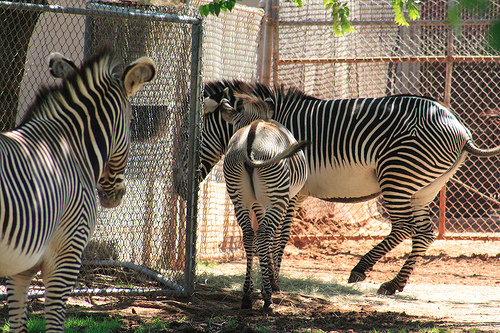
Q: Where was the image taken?
A: It was taken at the pen.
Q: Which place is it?
A: It is a pen.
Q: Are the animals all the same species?
A: Yes, all the animals are zebras.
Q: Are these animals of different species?
A: No, all the animals are zebras.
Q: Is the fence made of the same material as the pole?
A: Yes, both the fence and the pole are made of metal.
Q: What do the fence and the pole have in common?
A: The material, both the fence and the pole are metallic.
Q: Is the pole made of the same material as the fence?
A: Yes, both the pole and the fence are made of metal.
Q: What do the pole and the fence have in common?
A: The material, both the pole and the fence are metallic.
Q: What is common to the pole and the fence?
A: The material, both the pole and the fence are metallic.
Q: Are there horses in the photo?
A: No, there are no horses.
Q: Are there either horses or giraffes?
A: No, there are no horses or giraffes.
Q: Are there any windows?
A: Yes, there is a window.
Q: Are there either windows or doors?
A: Yes, there is a window.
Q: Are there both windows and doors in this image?
A: No, there is a window but no doors.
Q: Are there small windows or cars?
A: Yes, there is a small window.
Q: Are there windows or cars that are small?
A: Yes, the window is small.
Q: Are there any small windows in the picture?
A: Yes, there is a small window.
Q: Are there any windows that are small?
A: Yes, there is a window that is small.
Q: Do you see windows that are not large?
A: Yes, there is a small window.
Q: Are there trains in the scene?
A: No, there are no trains.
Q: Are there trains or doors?
A: No, there are no trains or doors.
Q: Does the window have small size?
A: Yes, the window is small.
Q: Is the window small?
A: Yes, the window is small.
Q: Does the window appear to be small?
A: Yes, the window is small.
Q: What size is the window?
A: The window is small.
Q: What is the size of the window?
A: The window is small.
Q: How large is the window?
A: The window is small.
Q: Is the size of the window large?
A: No, the window is small.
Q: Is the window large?
A: No, the window is small.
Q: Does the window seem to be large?
A: No, the window is small.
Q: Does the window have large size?
A: No, the window is small.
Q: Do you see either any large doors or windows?
A: No, there is a window but it is small.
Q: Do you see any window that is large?
A: No, there is a window but it is small.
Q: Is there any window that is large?
A: No, there is a window but it is small.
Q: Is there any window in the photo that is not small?
A: No, there is a window but it is small.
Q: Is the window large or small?
A: The window is small.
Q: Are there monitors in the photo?
A: No, there are no monitors.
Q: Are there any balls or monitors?
A: No, there are no monitors or balls.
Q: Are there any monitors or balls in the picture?
A: No, there are no monitors or balls.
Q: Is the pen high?
A: Yes, the pen is high.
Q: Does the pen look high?
A: Yes, the pen is high.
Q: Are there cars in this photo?
A: No, there are no cars.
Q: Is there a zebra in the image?
A: Yes, there is a zebra.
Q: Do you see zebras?
A: Yes, there is a zebra.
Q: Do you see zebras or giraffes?
A: Yes, there is a zebra.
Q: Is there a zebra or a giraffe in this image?
A: Yes, there is a zebra.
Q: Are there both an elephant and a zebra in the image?
A: No, there is a zebra but no elephants.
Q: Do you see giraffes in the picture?
A: No, there are no giraffes.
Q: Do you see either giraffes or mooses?
A: No, there are no giraffes or mooses.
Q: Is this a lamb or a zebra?
A: This is a zebra.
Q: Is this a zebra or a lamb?
A: This is a zebra.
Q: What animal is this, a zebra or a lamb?
A: This is a zebra.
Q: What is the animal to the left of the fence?
A: The animal is a zebra.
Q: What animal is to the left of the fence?
A: The animal is a zebra.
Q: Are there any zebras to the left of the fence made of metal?
A: Yes, there is a zebra to the left of the fence.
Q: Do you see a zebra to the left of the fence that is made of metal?
A: Yes, there is a zebra to the left of the fence.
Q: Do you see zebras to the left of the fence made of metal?
A: Yes, there is a zebra to the left of the fence.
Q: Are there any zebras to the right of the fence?
A: No, the zebra is to the left of the fence.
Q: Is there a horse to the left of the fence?
A: No, there is a zebra to the left of the fence.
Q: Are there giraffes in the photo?
A: No, there are no giraffes.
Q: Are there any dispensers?
A: No, there are no dispensers.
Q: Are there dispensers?
A: No, there are no dispensers.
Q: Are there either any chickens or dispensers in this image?
A: No, there are no dispensers or chickens.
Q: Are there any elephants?
A: No, there are no elephants.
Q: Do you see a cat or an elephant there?
A: No, there are no elephants or cats.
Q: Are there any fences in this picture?
A: Yes, there is a fence.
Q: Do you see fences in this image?
A: Yes, there is a fence.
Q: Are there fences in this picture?
A: Yes, there is a fence.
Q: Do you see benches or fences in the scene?
A: Yes, there is a fence.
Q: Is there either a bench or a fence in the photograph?
A: Yes, there is a fence.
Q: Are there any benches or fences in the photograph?
A: Yes, there is a fence.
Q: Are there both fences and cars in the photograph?
A: No, there is a fence but no cars.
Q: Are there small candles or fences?
A: Yes, there is a small fence.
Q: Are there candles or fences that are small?
A: Yes, the fence is small.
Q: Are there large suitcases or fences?
A: Yes, there is a large fence.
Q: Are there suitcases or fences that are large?
A: Yes, the fence is large.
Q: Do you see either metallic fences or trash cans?
A: Yes, there is a metal fence.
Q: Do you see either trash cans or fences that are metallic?
A: Yes, the fence is metallic.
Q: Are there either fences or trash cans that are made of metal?
A: Yes, the fence is made of metal.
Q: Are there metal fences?
A: Yes, there is a fence that is made of metal.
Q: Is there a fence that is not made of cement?
A: Yes, there is a fence that is made of metal.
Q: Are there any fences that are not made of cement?
A: Yes, there is a fence that is made of metal.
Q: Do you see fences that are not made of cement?
A: Yes, there is a fence that is made of metal.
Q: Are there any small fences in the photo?
A: Yes, there is a small fence.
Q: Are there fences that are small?
A: Yes, there is a fence that is small.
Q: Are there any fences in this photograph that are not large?
A: Yes, there is a small fence.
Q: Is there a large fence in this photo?
A: Yes, there is a large fence.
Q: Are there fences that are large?
A: Yes, there is a fence that is large.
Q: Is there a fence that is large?
A: Yes, there is a fence that is large.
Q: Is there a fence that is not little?
A: Yes, there is a large fence.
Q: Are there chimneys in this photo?
A: No, there are no chimneys.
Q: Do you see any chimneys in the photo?
A: No, there are no chimneys.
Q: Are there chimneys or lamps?
A: No, there are no chimneys or lamps.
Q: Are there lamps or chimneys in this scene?
A: No, there are no chimneys or lamps.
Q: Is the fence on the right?
A: Yes, the fence is on the right of the image.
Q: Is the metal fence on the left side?
A: No, the fence is on the right of the image.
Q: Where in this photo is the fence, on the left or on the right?
A: The fence is on the right of the image.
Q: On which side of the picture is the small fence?
A: The fence is on the right of the image.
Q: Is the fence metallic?
A: Yes, the fence is metallic.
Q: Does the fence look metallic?
A: Yes, the fence is metallic.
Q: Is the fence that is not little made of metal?
A: Yes, the fence is made of metal.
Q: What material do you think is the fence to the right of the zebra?
A: The fence is made of metal.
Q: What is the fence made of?
A: The fence is made of metal.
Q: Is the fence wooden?
A: No, the fence is metallic.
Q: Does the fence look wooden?
A: No, the fence is metallic.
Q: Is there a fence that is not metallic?
A: No, there is a fence but it is metallic.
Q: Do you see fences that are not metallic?
A: No, there is a fence but it is metallic.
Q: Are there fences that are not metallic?
A: No, there is a fence but it is metallic.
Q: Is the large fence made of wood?
A: No, the fence is made of metal.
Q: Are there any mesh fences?
A: No, there is a fence but it is made of metal.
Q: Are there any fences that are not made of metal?
A: No, there is a fence but it is made of metal.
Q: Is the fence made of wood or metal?
A: The fence is made of metal.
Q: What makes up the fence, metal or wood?
A: The fence is made of metal.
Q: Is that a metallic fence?
A: Yes, that is a metallic fence.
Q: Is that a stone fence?
A: No, that is a metallic fence.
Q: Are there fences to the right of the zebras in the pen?
A: Yes, there is a fence to the right of the zebras.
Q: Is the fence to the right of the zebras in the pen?
A: Yes, the fence is to the right of the zebras.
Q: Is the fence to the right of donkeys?
A: No, the fence is to the right of the zebras.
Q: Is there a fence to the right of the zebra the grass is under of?
A: Yes, there is a fence to the right of the zebra.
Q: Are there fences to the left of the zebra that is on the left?
A: No, the fence is to the right of the zebra.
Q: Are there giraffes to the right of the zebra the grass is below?
A: No, there is a fence to the right of the zebra.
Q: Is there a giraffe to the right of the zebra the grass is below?
A: No, there is a fence to the right of the zebra.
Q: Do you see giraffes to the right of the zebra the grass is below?
A: No, there is a fence to the right of the zebra.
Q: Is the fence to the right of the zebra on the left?
A: Yes, the fence is to the right of the zebra.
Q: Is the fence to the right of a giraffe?
A: No, the fence is to the right of the zebra.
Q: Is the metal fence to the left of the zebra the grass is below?
A: No, the fence is to the right of the zebra.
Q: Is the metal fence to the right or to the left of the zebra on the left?
A: The fence is to the right of the zebra.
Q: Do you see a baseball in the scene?
A: No, there are no baseballs.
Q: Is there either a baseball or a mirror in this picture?
A: No, there are no baseballs or mirrors.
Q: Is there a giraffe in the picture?
A: No, there are no giraffes.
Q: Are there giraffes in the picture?
A: No, there are no giraffes.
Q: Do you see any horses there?
A: No, there are no horses.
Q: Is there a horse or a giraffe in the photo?
A: No, there are no horses or giraffes.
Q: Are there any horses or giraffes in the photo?
A: No, there are no horses or giraffes.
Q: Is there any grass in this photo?
A: Yes, there is grass.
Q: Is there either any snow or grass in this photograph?
A: Yes, there is grass.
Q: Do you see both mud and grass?
A: No, there is grass but no mud.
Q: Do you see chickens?
A: No, there are no chickens.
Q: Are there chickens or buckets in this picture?
A: No, there are no chickens or buckets.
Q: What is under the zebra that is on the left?
A: The grass is under the zebra.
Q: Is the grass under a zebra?
A: Yes, the grass is under a zebra.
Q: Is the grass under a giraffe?
A: No, the grass is under a zebra.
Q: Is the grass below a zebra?
A: Yes, the grass is below a zebra.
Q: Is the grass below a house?
A: No, the grass is below a zebra.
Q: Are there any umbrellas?
A: No, there are no umbrellas.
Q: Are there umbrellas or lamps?
A: No, there are no umbrellas or lamps.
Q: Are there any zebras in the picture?
A: Yes, there are zebras.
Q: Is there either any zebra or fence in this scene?
A: Yes, there are zebras.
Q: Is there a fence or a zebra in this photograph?
A: Yes, there are zebras.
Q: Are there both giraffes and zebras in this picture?
A: No, there are zebras but no giraffes.